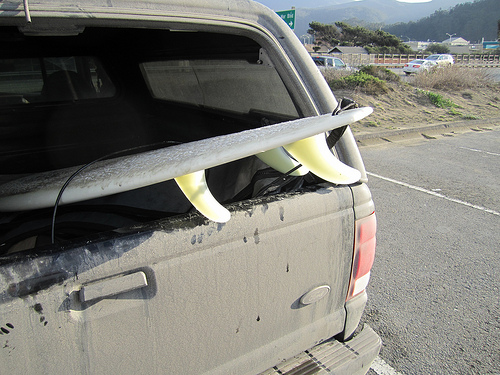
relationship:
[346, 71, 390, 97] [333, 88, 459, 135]
grass and dirt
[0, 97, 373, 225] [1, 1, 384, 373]
surfboard in back of suv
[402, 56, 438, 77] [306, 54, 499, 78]
car on street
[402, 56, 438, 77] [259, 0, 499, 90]
car in background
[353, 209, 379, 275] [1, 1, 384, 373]
brake lights on suv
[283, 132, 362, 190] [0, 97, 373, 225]
fin on surfboard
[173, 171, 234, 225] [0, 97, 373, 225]
fin on surfboard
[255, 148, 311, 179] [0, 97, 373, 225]
fin on surfboard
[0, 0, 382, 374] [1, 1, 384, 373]
dust covering suv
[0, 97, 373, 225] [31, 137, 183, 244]
surfboard has a cord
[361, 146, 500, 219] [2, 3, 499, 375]
lines in parking lot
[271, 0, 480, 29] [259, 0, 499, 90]
hills in background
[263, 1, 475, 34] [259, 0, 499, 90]
mountains in background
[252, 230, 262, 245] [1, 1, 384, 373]
spots on suv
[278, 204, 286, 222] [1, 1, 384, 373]
spots on suv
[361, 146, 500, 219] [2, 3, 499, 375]
stripe in parking lot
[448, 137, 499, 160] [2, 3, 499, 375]
stripe in parking lot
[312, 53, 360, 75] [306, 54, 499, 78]
car on a road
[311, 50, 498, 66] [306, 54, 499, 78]
fence alongside road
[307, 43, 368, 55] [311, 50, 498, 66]
house behind fence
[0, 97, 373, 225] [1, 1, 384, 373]
board in truck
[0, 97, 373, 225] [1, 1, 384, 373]
surfboard hanging out of car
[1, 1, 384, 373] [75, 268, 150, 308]
car has a handle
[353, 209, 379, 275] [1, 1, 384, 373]
light on back of car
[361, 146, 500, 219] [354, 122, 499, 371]
line on road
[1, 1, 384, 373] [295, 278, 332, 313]
car has a brand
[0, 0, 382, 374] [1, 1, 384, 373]
dust on back of car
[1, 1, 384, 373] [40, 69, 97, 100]
car has a front seat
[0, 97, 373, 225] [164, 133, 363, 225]
surfboard with fins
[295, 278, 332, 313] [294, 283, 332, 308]
ford logo covered in dust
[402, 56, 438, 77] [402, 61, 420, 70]
car with tail lights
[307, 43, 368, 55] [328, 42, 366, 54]
house with roof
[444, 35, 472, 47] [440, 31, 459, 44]
house with roof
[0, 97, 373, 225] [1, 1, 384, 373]
surfboard in back of truck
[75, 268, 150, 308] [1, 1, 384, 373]
latch on suv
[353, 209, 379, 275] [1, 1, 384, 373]
brake lights on rear of ford truck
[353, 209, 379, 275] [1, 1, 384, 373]
brake lights on right of ford truck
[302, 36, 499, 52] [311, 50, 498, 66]
residential area behind fence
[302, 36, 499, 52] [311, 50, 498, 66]
residential area across fence